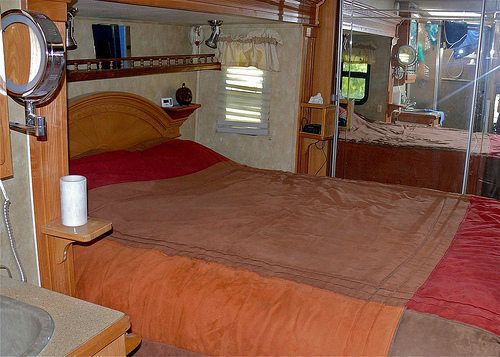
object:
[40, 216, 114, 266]
stand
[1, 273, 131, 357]
countertop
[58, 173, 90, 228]
candle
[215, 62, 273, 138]
window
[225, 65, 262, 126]
sun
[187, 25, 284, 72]
beige topper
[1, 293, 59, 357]
gray sink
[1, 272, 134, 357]
wood edge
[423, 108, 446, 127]
rag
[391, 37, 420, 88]
mirror reflection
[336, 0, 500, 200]
mirror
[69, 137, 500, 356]
cover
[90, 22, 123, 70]
book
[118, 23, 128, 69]
book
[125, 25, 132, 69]
book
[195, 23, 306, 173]
wall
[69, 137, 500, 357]
bedspread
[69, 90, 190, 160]
head board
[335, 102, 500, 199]
bed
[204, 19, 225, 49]
lights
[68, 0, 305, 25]
ceiling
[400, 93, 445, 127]
reflection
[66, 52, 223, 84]
bookshelf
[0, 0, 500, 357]
room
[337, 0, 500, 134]
wall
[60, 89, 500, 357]
bed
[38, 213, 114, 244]
shelf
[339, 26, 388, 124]
doors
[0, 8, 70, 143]
mirror